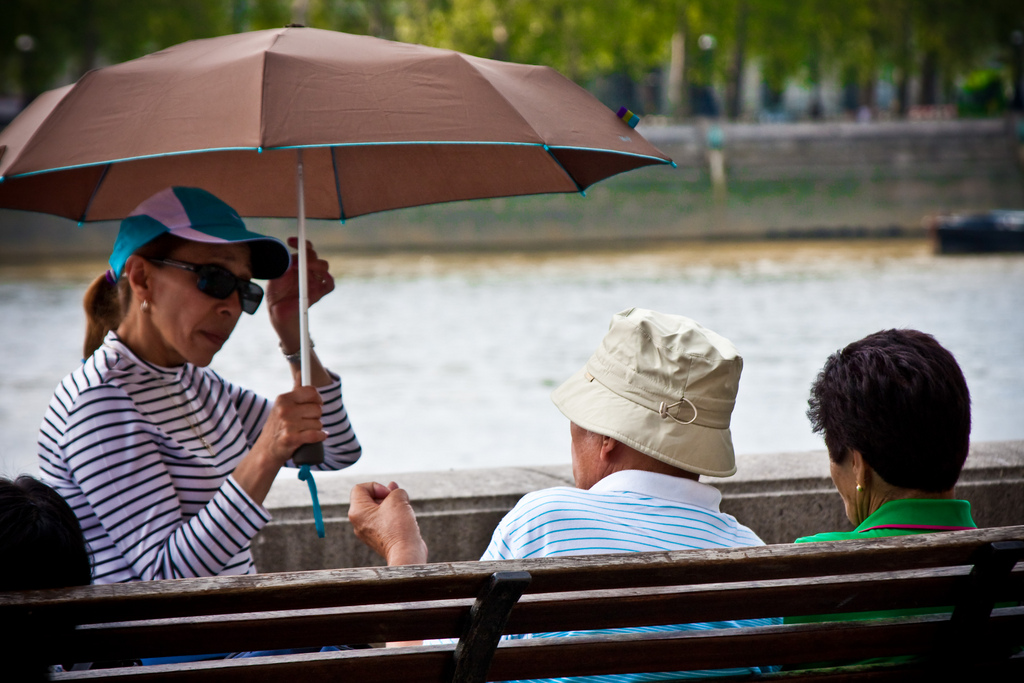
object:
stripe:
[63, 384, 126, 416]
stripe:
[63, 397, 132, 431]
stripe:
[68, 435, 140, 481]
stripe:
[219, 478, 266, 525]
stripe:
[206, 489, 233, 539]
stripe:
[191, 515, 234, 564]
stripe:
[172, 522, 210, 572]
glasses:
[143, 257, 263, 315]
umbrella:
[0, 25, 679, 465]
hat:
[109, 186, 293, 282]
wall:
[0, 119, 1024, 257]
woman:
[36, 186, 364, 586]